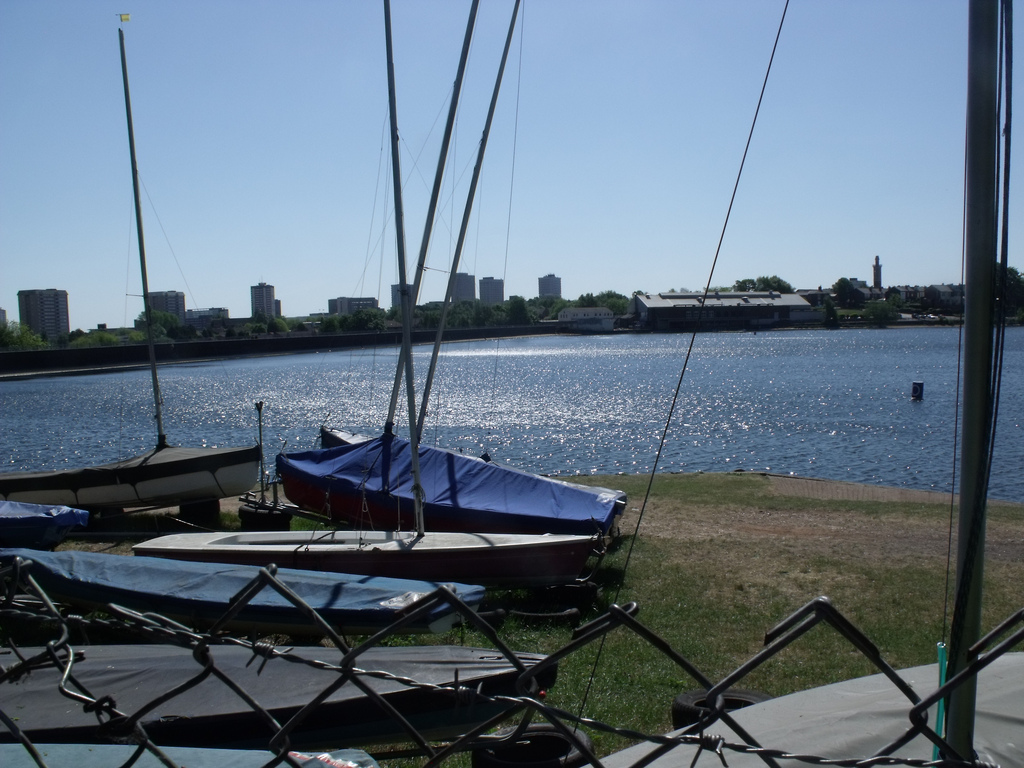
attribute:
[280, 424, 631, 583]
boat — small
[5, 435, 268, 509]
boat — small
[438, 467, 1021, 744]
grass — green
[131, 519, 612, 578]
boat — small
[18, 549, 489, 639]
boat — small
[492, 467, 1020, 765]
grass — green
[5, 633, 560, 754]
boat — small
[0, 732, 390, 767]
boat — small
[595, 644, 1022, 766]
boat — small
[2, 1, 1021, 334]
sky — blue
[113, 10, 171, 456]
mast — tall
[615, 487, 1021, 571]
dirt — brown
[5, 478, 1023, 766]
grass — brown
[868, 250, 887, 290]
steeple — tall, in distance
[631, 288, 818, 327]
building — long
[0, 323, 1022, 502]
water — glistening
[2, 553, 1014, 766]
fence — chain link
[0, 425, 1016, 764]
boats — sailboat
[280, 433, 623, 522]
cover — blue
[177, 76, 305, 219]
clouds — white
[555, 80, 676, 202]
clouds — white